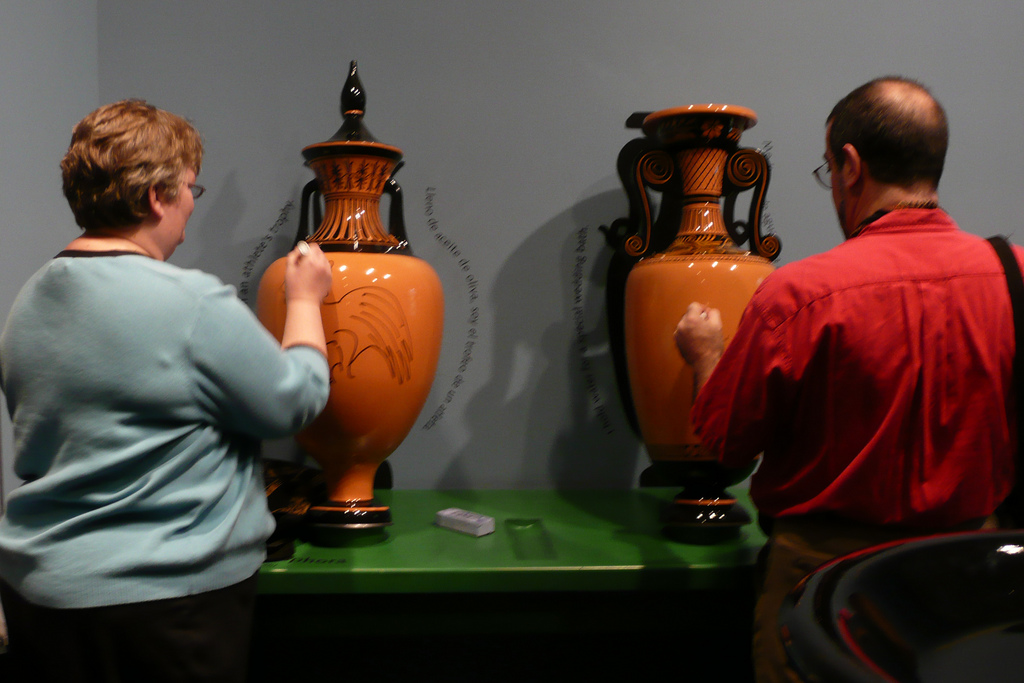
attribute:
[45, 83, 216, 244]
hair — short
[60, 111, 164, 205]
hair — blonde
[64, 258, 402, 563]
shirt — blue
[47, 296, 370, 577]
shirt — long sleeve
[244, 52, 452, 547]
pot — large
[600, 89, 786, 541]
pot — large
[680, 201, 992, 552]
shirt — red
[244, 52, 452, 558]
urn — decorative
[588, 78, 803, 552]
urn — decorative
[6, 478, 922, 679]
table — green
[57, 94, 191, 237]
hair — short  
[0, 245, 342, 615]
sweater — cyan, blue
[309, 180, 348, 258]
stripe — black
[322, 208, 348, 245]
stripe — black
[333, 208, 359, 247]
stripe — black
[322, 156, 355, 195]
stripe — black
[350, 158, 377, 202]
stripe — black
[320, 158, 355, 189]
stripe — black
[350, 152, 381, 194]
stripe — black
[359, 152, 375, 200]
stripe — black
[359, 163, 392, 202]
stripe — black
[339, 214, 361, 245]
stripe — black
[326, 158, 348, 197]
stripe — black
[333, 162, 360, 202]
stripe — black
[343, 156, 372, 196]
stripe — black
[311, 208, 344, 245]
stripe — black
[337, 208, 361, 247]
stripe — black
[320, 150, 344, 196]
stripe — black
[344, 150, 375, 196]
stripe — black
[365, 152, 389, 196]
stripe — black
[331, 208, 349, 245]
stripe — black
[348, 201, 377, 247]
stripe — black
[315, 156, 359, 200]
stripe — black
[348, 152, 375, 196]
stripe — black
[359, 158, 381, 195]
stripe — black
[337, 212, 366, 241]
stripe — black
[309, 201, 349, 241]
stripe — black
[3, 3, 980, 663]
picture — taken indoors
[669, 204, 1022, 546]
shirt — red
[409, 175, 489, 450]
lettering — black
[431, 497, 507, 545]
box — grey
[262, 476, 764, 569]
table — green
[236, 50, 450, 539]
vase — orange, large, brown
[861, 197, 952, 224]
string — black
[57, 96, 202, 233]
hair — brownish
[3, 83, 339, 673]
woman — standing, overweight 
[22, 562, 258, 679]
pants — black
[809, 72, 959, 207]
hair — short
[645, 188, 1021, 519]
shirt — red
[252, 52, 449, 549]
vase — orange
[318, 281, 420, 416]
design — decorative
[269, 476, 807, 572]
table — green